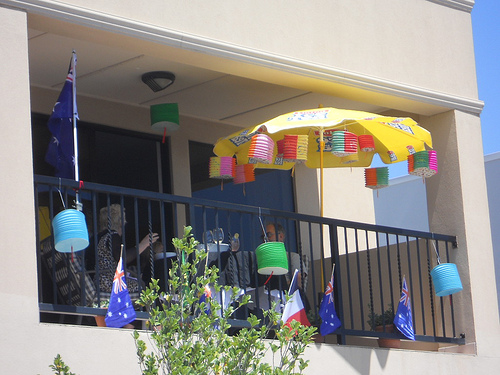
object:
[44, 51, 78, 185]
flag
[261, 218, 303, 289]
person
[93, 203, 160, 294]
person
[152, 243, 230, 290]
table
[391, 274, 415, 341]
flags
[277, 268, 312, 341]
flags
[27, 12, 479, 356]
balcony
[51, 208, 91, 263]
decoration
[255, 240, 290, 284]
decoration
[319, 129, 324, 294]
shaft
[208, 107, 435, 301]
umbrella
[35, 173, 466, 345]
rail